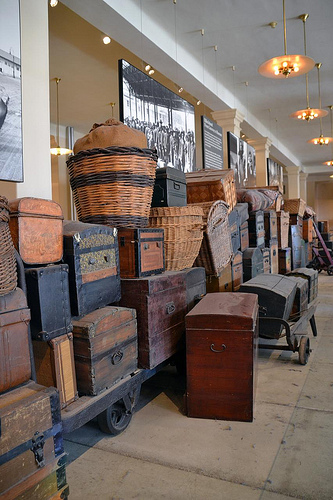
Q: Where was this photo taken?
A: Inside a store.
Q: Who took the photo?
A: Someone interested in the chests.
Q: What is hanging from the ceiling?
A: Lights.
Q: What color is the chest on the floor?
A: Brown.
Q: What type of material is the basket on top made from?
A: Wicker.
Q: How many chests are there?
A: At least 100.